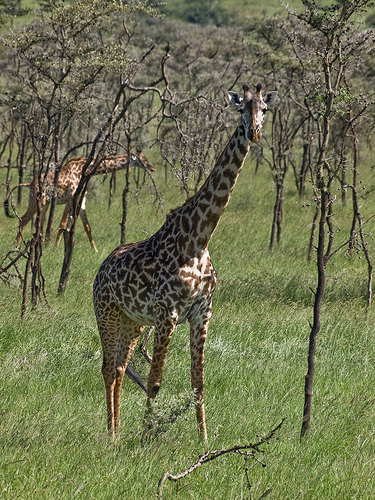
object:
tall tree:
[0, 1, 146, 318]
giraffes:
[3, 82, 278, 447]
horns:
[242, 82, 262, 93]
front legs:
[143, 299, 213, 450]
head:
[226, 83, 278, 144]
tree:
[174, 0, 297, 200]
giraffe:
[4, 145, 157, 253]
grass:
[0, 75, 375, 499]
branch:
[156, 417, 285, 498]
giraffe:
[92, 83, 278, 452]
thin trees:
[269, 0, 375, 269]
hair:
[3, 199, 16, 218]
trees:
[1, 0, 374, 443]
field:
[0, 0, 375, 498]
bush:
[140, 392, 195, 449]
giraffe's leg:
[145, 310, 177, 412]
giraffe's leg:
[186, 302, 214, 446]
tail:
[3, 181, 32, 219]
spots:
[172, 226, 202, 268]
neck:
[187, 119, 253, 260]